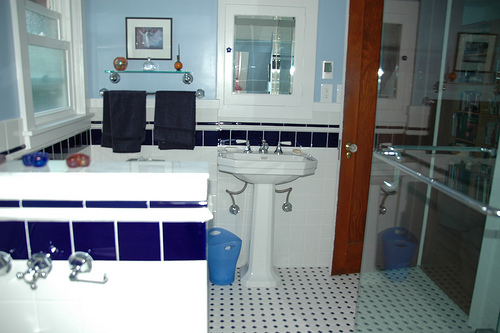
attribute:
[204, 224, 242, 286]
trash can — blue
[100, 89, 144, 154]
towel — dark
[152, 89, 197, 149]
towel — dark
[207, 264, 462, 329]
tile — grey, white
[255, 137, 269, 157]
silver faucet — on bathroom sink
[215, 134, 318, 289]
bathroom sink — white, pedestal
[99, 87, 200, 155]
towels — dark blue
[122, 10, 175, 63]
small picture — with frame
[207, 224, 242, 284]
wastepaper basket — small blue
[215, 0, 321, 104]
medicine cabinet — built in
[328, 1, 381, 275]
wooden door — brown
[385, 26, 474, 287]
reflection/bathroom objects — in shower door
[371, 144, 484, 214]
handle — long, chrome colored, on shower door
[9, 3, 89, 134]
window — in wall, with white frame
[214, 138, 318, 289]
pedestal sink — white, in bathroom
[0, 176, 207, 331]
tiled wall — white and blue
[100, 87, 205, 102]
towel rack — hanging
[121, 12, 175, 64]
art — framed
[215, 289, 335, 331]
tiled floor — black and white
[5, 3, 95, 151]
framed window — white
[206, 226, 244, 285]
trash can — blue, plastic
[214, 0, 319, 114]
medicine cabinet — white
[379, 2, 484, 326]
shower enclosure — glass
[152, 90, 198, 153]
black towel — on a rack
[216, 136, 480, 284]
pedestal sink — white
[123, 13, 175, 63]
picture — framed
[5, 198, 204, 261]
tile — blue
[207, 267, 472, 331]
floor — tiled, white, black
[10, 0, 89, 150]
window — framed, white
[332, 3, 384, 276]
door — wooden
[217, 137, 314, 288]
sink — bathroom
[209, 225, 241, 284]
basket — blue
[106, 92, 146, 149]
towel — grey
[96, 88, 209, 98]
rack — grey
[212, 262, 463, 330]
floor — bathroom, white, blue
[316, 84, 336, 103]
plug — for power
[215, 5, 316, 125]
cabinet — white, for medicine